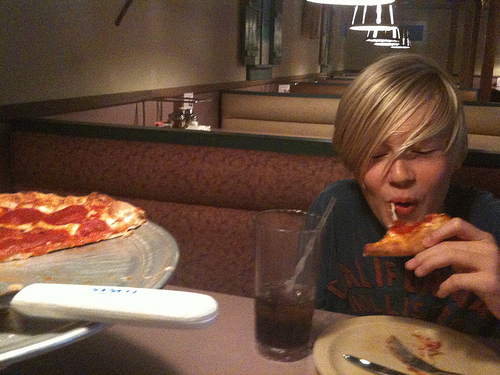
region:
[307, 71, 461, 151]
his hair is blonde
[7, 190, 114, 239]
pepperonis on the pizza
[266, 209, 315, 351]
his drink is almost gone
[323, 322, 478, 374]
the plate is paper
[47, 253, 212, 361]
the handle is white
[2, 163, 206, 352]
pizza on the platter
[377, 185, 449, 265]
he is eating a piece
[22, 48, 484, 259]
they are in a pizza parlor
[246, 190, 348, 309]
straw in his cup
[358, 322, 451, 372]
he used two utensils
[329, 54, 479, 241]
head of a person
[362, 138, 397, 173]
eye of a person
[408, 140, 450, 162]
eye of a person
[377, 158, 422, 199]
nose of a person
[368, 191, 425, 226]
mouth of a person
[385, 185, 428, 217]
lips of a person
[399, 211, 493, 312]
hand of a person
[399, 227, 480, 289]
finger of a person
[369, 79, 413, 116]
hair of a person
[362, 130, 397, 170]
an eye of a person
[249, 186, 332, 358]
A clear glass on table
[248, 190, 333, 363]
A beverage on the table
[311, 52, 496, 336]
A man eating pizza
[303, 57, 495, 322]
Teen eating slice of pizza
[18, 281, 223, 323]
Handle of a pizza server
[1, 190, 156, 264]
Pizza on a plate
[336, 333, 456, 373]
Silverware on a plate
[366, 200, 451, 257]
Partially eaten piece of pizza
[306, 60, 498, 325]
Teen with blonde hair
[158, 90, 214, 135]
Condiments on a table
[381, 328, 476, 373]
Fork on a plate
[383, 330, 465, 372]
Fork is on a plate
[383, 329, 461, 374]
Fork on a round plate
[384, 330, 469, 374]
Fork is on a round plate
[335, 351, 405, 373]
Knife on a plate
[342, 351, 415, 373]
Knife is on a plate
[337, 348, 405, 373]
Knife on a round plate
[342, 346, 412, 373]
Knife is on a round plate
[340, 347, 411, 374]
Butter knife on a plate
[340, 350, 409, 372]
Butter knife is on a plate